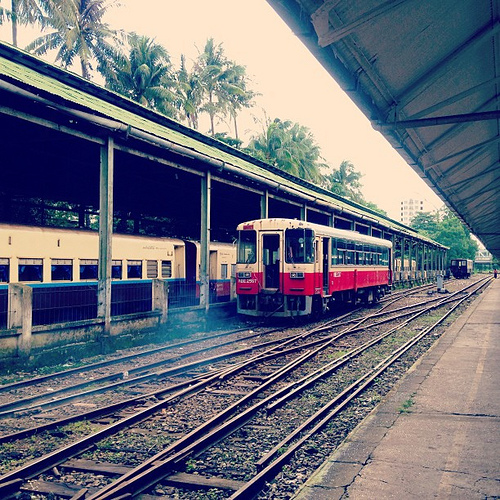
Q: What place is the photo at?
A: It is at the station.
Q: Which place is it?
A: It is a station.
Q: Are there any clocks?
A: No, there are no clocks.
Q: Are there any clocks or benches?
A: No, there are no clocks or benches.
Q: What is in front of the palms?
A: The station is in front of the palms.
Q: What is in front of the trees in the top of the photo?
A: The station is in front of the palms.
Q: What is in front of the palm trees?
A: The station is in front of the palms.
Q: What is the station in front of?
A: The station is in front of the palms.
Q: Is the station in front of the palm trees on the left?
A: Yes, the station is in front of the palms.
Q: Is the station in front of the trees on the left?
A: Yes, the station is in front of the palms.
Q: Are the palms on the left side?
A: Yes, the palms are on the left of the image.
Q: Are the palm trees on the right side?
A: No, the palm trees are on the left of the image.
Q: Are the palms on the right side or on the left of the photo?
A: The palms are on the left of the image.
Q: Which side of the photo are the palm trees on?
A: The palm trees are on the left of the image.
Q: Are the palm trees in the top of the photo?
A: Yes, the palm trees are in the top of the image.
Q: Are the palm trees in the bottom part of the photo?
A: No, the palm trees are in the top of the image.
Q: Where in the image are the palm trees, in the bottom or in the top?
A: The palm trees are in the top of the image.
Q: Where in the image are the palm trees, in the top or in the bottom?
A: The palm trees are in the top of the image.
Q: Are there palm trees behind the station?
A: Yes, there are palm trees behind the station.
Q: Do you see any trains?
A: Yes, there are trains.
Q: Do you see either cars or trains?
A: Yes, there are trains.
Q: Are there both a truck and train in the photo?
A: No, there are trains but no trucks.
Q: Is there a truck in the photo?
A: No, there are no trucks.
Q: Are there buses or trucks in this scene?
A: No, there are no trucks or buses.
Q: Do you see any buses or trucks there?
A: No, there are no trucks or buses.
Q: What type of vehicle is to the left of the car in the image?
A: The vehicles are trains.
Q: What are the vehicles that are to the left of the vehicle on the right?
A: The vehicles are trains.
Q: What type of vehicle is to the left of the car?
A: The vehicles are trains.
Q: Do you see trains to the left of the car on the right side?
A: Yes, there are trains to the left of the car.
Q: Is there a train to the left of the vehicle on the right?
A: Yes, there are trains to the left of the car.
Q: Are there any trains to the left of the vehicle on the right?
A: Yes, there are trains to the left of the car.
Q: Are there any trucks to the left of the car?
A: No, there are trains to the left of the car.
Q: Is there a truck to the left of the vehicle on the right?
A: No, there are trains to the left of the car.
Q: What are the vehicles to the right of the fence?
A: The vehicles are trains.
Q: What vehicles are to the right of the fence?
A: The vehicles are trains.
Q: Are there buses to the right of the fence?
A: No, there are trains to the right of the fence.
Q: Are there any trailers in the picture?
A: No, there are no trailers.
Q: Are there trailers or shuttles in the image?
A: No, there are no trailers or shuttles.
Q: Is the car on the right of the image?
A: Yes, the car is on the right of the image.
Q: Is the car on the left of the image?
A: No, the car is on the right of the image.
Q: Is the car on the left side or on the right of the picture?
A: The car is on the right of the image.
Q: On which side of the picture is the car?
A: The car is on the right of the image.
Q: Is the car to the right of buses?
A: No, the car is to the right of the trains.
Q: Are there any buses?
A: No, there are no buses.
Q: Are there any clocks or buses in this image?
A: No, there are no buses or clocks.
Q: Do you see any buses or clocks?
A: No, there are no buses or clocks.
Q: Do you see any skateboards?
A: No, there are no skateboards.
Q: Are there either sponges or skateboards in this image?
A: No, there are no skateboards or sponges.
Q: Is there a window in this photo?
A: Yes, there is a window.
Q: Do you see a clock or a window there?
A: Yes, there is a window.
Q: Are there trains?
A: Yes, there is a train.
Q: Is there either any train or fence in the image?
A: Yes, there is a train.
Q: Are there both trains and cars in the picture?
A: Yes, there are both a train and a car.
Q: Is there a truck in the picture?
A: No, there are no trucks.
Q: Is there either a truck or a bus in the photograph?
A: No, there are no trucks or buses.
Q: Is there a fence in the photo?
A: Yes, there is a fence.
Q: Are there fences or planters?
A: Yes, there is a fence.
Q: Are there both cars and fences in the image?
A: Yes, there are both a fence and a car.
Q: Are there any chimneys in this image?
A: No, there are no chimneys.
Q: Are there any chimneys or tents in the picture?
A: No, there are no chimneys or tents.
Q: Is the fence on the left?
A: Yes, the fence is on the left of the image.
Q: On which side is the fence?
A: The fence is on the left of the image.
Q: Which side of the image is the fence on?
A: The fence is on the left of the image.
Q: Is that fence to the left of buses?
A: No, the fence is to the left of the trains.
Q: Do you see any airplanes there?
A: No, there are no airplanes.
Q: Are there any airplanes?
A: No, there are no airplanes.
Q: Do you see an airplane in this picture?
A: No, there are no airplanes.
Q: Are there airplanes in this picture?
A: No, there are no airplanes.